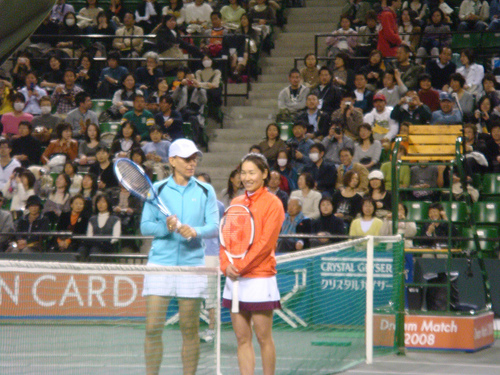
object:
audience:
[11, 86, 147, 234]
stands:
[4, 3, 491, 245]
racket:
[110, 158, 192, 235]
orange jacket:
[218, 188, 285, 278]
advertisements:
[0, 232, 499, 353]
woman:
[348, 196, 383, 233]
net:
[0, 236, 373, 374]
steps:
[194, 0, 347, 198]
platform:
[389, 160, 463, 305]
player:
[134, 130, 221, 374]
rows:
[0, 0, 500, 249]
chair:
[0, 0, 499, 265]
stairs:
[188, 0, 354, 200]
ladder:
[398, 169, 460, 317]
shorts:
[140, 262, 207, 298]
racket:
[216, 207, 256, 311]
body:
[219, 191, 286, 311]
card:
[31, 275, 138, 308]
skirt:
[217, 273, 285, 317]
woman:
[216, 150, 286, 374]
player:
[217, 155, 286, 373]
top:
[219, 188, 264, 266]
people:
[0, 0, 499, 254]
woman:
[111, 136, 221, 373]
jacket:
[139, 172, 219, 267]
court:
[0, 316, 499, 375]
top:
[161, 189, 195, 236]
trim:
[220, 303, 283, 313]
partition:
[64, 262, 220, 272]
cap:
[165, 138, 203, 159]